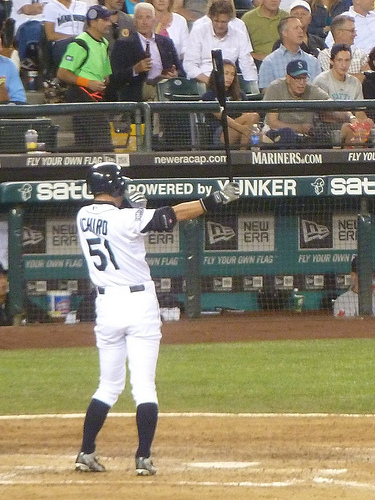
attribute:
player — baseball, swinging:
[75, 162, 240, 475]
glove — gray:
[214, 182, 242, 205]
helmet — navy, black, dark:
[86, 163, 132, 197]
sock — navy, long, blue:
[134, 402, 157, 462]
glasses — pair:
[287, 72, 309, 83]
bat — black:
[210, 49, 238, 201]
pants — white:
[90, 284, 162, 406]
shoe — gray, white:
[75, 452, 108, 473]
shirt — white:
[75, 202, 155, 286]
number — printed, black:
[86, 237, 122, 273]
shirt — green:
[60, 30, 112, 88]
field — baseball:
[2, 317, 374, 499]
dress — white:
[77, 204, 162, 406]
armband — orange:
[75, 75, 91, 87]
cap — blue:
[86, 6, 118, 22]